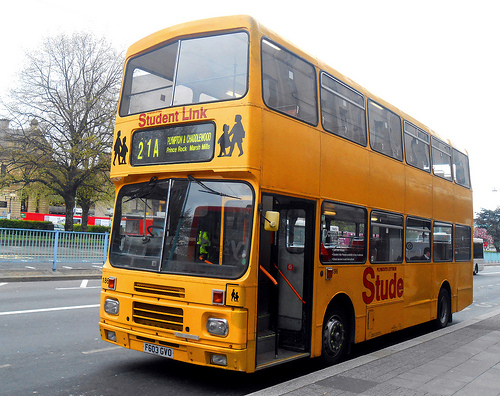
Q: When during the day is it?
A: Afternoon.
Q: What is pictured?
A: An autobus.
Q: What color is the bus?
A: Yellow.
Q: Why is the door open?
A: For passenger.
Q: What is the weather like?
A: Overcast.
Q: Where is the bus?
A: Along the street.